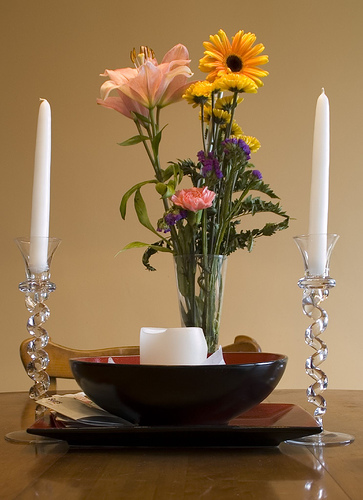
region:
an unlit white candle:
[301, 80, 339, 278]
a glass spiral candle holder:
[285, 262, 353, 465]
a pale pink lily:
[87, 37, 188, 137]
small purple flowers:
[169, 136, 273, 176]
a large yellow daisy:
[184, 20, 287, 91]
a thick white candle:
[122, 314, 223, 374]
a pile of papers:
[37, 382, 139, 443]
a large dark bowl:
[58, 334, 297, 424]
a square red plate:
[25, 387, 339, 451]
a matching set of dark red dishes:
[8, 336, 361, 448]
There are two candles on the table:
[26, 86, 360, 470]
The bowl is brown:
[66, 346, 338, 444]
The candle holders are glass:
[277, 274, 358, 376]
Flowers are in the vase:
[107, 53, 304, 313]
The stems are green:
[112, 112, 298, 264]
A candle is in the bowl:
[115, 313, 260, 400]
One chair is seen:
[9, 323, 319, 397]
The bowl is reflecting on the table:
[13, 391, 358, 487]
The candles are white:
[21, 95, 330, 356]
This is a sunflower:
[203, 29, 274, 144]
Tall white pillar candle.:
[296, 82, 332, 278]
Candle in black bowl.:
[69, 324, 287, 423]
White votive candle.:
[138, 325, 210, 361]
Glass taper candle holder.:
[289, 231, 355, 450]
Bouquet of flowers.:
[97, 28, 295, 343]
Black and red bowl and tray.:
[22, 351, 321, 455]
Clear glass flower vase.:
[170, 252, 228, 352]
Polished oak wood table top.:
[0, 390, 360, 494]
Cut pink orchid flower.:
[91, 41, 188, 183]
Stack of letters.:
[33, 388, 131, 432]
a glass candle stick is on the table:
[283, 233, 352, 445]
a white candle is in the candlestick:
[294, 87, 339, 273]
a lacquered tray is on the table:
[21, 402, 321, 449]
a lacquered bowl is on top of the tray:
[69, 350, 287, 420]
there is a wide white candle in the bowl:
[136, 324, 207, 365]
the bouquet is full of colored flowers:
[102, 24, 291, 263]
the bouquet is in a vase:
[97, 30, 290, 346]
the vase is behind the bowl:
[171, 253, 227, 352]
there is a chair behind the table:
[17, 334, 262, 388]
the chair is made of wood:
[19, 334, 263, 394]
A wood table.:
[72, 453, 275, 492]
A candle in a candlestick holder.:
[288, 83, 348, 443]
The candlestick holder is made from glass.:
[284, 227, 345, 441]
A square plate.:
[31, 390, 312, 438]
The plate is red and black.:
[25, 396, 325, 442]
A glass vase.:
[168, 248, 237, 339]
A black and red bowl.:
[69, 339, 287, 412]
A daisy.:
[199, 17, 267, 83]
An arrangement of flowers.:
[100, 18, 291, 260]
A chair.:
[16, 327, 271, 389]